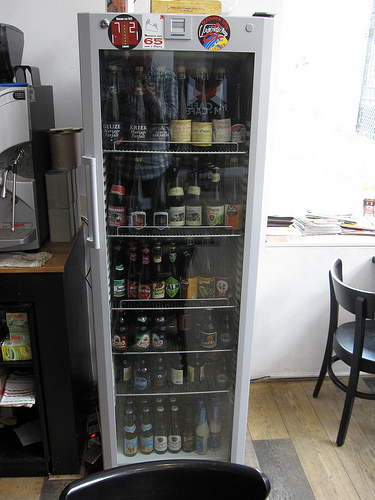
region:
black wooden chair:
[311, 259, 374, 444]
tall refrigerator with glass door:
[76, 12, 274, 467]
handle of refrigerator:
[81, 155, 101, 249]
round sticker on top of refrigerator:
[197, 14, 230, 49]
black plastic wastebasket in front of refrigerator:
[57, 458, 271, 498]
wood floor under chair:
[246, 378, 374, 499]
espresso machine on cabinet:
[0, 23, 49, 252]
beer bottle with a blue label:
[122, 407, 140, 455]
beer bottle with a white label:
[153, 405, 171, 451]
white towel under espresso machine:
[0, 250, 53, 267]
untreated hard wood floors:
[271, 393, 317, 470]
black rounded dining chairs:
[319, 261, 373, 408]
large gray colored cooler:
[79, 30, 241, 463]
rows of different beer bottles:
[107, 83, 204, 454]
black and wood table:
[14, 251, 93, 462]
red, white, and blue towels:
[10, 379, 40, 439]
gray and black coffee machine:
[0, 73, 73, 232]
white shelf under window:
[277, 194, 374, 266]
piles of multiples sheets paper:
[295, 196, 345, 263]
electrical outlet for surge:
[76, 395, 118, 462]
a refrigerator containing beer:
[84, 20, 257, 455]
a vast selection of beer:
[110, 60, 232, 451]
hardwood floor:
[267, 396, 332, 481]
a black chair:
[322, 257, 371, 446]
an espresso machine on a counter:
[1, 20, 43, 245]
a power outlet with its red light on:
[82, 407, 102, 453]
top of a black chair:
[60, 465, 293, 497]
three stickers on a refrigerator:
[107, 15, 237, 49]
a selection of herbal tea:
[0, 302, 34, 368]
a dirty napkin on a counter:
[1, 250, 57, 271]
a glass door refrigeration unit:
[79, 10, 269, 465]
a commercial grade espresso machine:
[0, 26, 76, 253]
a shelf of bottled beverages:
[102, 61, 249, 152]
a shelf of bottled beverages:
[101, 154, 243, 234]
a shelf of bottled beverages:
[107, 238, 237, 307]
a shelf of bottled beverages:
[108, 310, 233, 349]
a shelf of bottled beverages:
[111, 355, 233, 392]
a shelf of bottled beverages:
[118, 399, 231, 460]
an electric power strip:
[80, 405, 101, 471]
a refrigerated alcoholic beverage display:
[76, 9, 268, 471]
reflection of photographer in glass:
[99, 45, 178, 281]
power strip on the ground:
[79, 397, 101, 452]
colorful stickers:
[102, 12, 235, 51]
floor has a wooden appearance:
[247, 376, 367, 493]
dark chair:
[312, 255, 372, 447]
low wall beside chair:
[261, 234, 371, 399]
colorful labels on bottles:
[109, 259, 196, 296]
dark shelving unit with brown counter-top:
[0, 227, 84, 469]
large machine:
[0, 22, 84, 273]